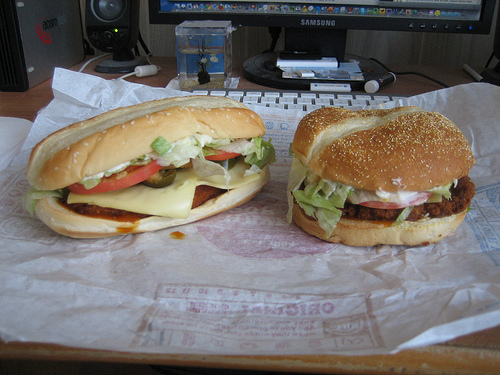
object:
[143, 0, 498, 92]
television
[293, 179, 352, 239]
cabbage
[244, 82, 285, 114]
lettuce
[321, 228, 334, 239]
lettuce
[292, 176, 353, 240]
vegetable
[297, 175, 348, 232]
lettuce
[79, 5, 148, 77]
speaker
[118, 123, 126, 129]
sesame seed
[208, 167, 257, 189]
provolone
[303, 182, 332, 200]
lettuce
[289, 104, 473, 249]
sandwich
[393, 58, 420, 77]
ground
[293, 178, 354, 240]
lettuce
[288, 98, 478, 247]
bn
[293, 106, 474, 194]
bread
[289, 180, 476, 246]
bread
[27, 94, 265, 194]
bread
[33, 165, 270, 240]
bread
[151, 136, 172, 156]
lettuce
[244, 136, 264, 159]
lettuce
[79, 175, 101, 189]
lettuce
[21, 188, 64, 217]
lettuce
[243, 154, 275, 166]
lettuce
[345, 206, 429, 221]
meat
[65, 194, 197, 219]
cheese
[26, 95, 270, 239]
hamburger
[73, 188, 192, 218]
provolone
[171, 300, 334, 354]
inaccurate sentence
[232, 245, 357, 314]
inaccurate sentence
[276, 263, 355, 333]
noteverypictureisofthelettuce!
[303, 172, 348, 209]
provolone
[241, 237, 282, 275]
paper